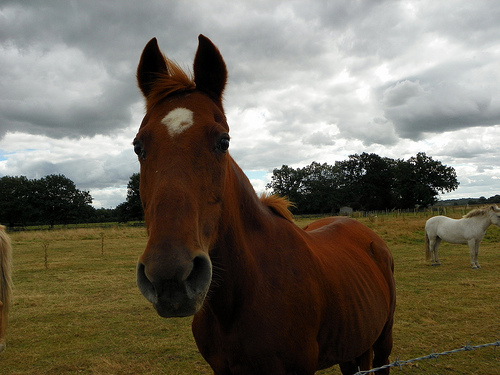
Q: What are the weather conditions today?
A: It is cloudy.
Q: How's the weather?
A: It is cloudy.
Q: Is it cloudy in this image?
A: Yes, it is cloudy.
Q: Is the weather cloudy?
A: Yes, it is cloudy.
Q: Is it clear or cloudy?
A: It is cloudy.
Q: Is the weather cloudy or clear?
A: It is cloudy.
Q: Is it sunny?
A: No, it is cloudy.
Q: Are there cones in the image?
A: No, there are no cones.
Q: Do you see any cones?
A: No, there are no cones.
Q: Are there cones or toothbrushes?
A: No, there are no cones or toothbrushes.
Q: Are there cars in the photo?
A: No, there are no cars.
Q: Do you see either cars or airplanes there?
A: No, there are no cars or airplanes.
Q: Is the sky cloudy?
A: Yes, the sky is cloudy.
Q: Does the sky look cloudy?
A: Yes, the sky is cloudy.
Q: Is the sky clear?
A: No, the sky is cloudy.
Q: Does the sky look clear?
A: No, the sky is cloudy.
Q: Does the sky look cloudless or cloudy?
A: The sky is cloudy.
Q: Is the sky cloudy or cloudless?
A: The sky is cloudy.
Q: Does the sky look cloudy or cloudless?
A: The sky is cloudy.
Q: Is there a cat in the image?
A: No, there are no cats.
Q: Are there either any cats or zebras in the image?
A: No, there are no cats or zebras.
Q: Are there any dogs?
A: No, there are no dogs.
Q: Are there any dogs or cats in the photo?
A: No, there are no dogs or cats.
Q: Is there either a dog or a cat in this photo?
A: No, there are no dogs or cats.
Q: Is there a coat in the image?
A: Yes, there is a coat.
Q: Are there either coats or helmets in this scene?
A: Yes, there is a coat.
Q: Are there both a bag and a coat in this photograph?
A: No, there is a coat but no bags.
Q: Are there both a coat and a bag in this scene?
A: No, there is a coat but no bags.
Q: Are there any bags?
A: No, there are no bags.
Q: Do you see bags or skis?
A: No, there are no bags or skis.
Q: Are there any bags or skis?
A: No, there are no bags or skis.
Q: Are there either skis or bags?
A: No, there are no bags or skis.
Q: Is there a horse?
A: Yes, there is a horse.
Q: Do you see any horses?
A: Yes, there is a horse.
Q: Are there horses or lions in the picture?
A: Yes, there is a horse.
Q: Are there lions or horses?
A: Yes, there is a horse.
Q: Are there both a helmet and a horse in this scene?
A: No, there is a horse but no helmets.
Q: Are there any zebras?
A: No, there are no zebras.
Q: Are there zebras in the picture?
A: No, there are no zebras.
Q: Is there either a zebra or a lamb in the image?
A: No, there are no zebras or lambs.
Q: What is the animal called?
A: The animal is a horse.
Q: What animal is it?
A: The animal is a horse.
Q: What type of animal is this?
A: This is a horse.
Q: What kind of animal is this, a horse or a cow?
A: This is a horse.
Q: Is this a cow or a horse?
A: This is a horse.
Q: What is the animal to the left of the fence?
A: The animal is a horse.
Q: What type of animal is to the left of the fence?
A: The animal is a horse.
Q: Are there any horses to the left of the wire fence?
A: Yes, there is a horse to the left of the fence.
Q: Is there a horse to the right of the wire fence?
A: No, the horse is to the left of the fence.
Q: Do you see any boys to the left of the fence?
A: No, there is a horse to the left of the fence.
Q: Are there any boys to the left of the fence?
A: No, there is a horse to the left of the fence.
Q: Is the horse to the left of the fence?
A: Yes, the horse is to the left of the fence.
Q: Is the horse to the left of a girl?
A: No, the horse is to the left of the fence.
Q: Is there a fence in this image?
A: Yes, there is a fence.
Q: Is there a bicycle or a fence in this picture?
A: Yes, there is a fence.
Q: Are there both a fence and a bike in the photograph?
A: No, there is a fence but no bikes.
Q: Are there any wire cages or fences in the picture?
A: Yes, there is a wire fence.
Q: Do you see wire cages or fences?
A: Yes, there is a wire fence.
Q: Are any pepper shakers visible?
A: No, there are no pepper shakers.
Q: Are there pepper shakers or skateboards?
A: No, there are no pepper shakers or skateboards.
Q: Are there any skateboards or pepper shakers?
A: No, there are no pepper shakers or skateboards.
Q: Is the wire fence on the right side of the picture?
A: Yes, the fence is on the right of the image.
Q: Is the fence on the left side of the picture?
A: No, the fence is on the right of the image.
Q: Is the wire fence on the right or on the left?
A: The fence is on the right of the image.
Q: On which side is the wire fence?
A: The fence is on the right of the image.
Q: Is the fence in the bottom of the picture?
A: Yes, the fence is in the bottom of the image.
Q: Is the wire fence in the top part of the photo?
A: No, the fence is in the bottom of the image.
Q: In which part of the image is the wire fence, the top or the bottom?
A: The fence is in the bottom of the image.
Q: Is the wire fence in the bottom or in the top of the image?
A: The fence is in the bottom of the image.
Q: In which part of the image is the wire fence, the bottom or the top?
A: The fence is in the bottom of the image.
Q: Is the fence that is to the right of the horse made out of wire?
A: Yes, the fence is made of wire.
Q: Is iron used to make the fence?
A: No, the fence is made of wire.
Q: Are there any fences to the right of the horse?
A: Yes, there is a fence to the right of the horse.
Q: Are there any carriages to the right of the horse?
A: No, there is a fence to the right of the horse.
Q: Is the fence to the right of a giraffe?
A: No, the fence is to the right of the horse.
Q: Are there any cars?
A: No, there are no cars.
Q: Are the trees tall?
A: Yes, the trees are tall.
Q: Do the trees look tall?
A: Yes, the trees are tall.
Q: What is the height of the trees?
A: The trees are tall.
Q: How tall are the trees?
A: The trees are tall.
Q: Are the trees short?
A: No, the trees are tall.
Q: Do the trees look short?
A: No, the trees are tall.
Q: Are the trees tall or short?
A: The trees are tall.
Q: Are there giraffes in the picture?
A: No, there are no giraffes.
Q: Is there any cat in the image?
A: No, there are no cats.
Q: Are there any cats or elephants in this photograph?
A: No, there are no cats or elephants.